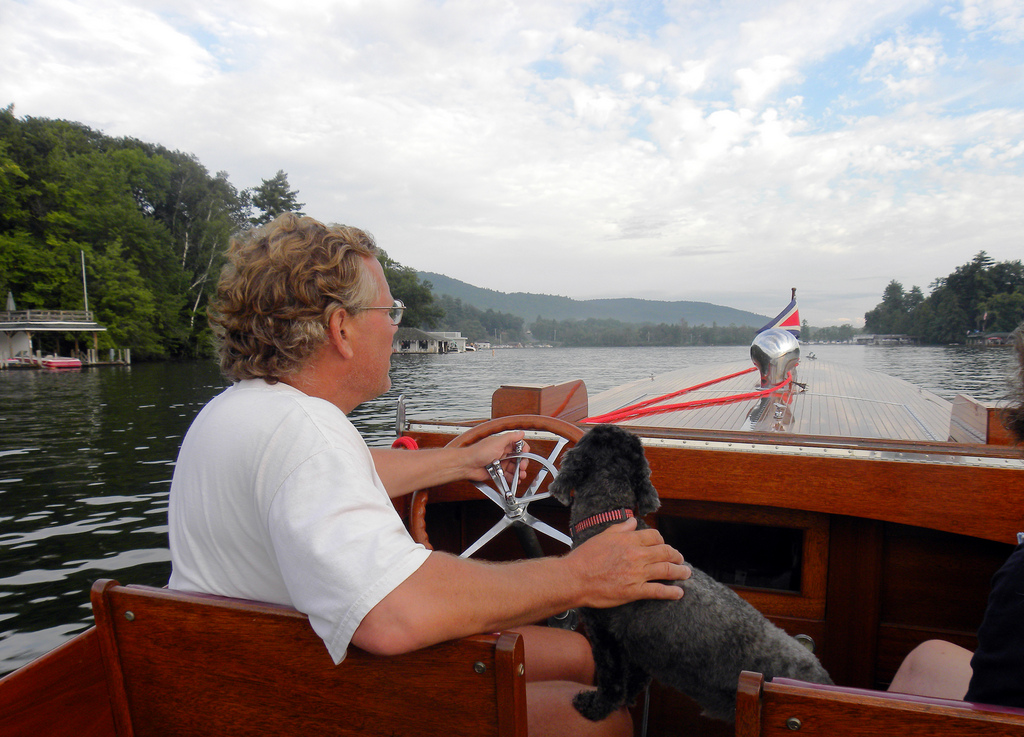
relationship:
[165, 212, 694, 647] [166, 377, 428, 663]
person wearing shirt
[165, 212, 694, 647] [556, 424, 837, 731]
person petting dog